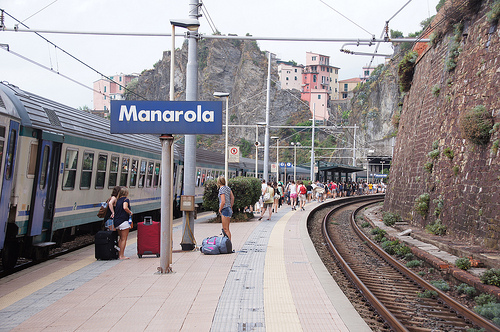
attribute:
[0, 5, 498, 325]
scene — outdoors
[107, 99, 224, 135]
sign — blue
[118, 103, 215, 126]
letters — white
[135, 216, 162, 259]
suitcase — red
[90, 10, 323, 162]
rock — large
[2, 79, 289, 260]
train — for passengers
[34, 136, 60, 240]
door — blue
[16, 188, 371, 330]
platform — concrete, passenger loading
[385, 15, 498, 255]
wall — red brick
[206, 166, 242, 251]
woman — blonde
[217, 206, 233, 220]
shorts — short, jean